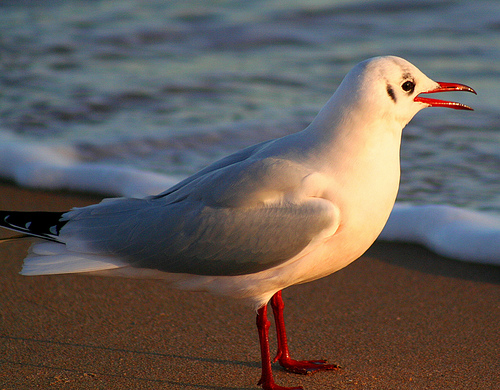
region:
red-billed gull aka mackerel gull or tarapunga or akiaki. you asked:
[4, 51, 485, 388]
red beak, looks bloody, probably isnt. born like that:
[413, 80, 480, 118]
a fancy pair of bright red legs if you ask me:
[230, 289, 360, 389]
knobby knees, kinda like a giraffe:
[253, 287, 288, 334]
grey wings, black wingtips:
[0, 140, 346, 285]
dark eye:
[398, 80, 414, 93]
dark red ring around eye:
[394, 72, 417, 100]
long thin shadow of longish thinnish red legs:
[0, 330, 337, 385]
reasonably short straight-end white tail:
[7, 236, 128, 278]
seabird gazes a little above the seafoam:
[1, 122, 498, 273]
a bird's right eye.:
[396, 71, 421, 100]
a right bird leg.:
[250, 298, 275, 388]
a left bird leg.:
[268, 270, 311, 389]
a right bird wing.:
[54, 149, 340, 318]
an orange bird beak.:
[409, 69, 489, 132]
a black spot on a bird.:
[382, 84, 399, 111]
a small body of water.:
[0, 0, 498, 285]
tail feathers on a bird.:
[7, 212, 134, 292]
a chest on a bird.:
[313, 162, 410, 276]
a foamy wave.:
[2, 128, 495, 268]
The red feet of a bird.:
[237, 294, 354, 389]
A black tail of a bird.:
[5, 194, 109, 294]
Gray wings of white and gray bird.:
[79, 171, 380, 268]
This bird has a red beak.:
[426, 72, 483, 122]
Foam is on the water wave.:
[0, 116, 173, 195]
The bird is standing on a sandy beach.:
[5, 278, 498, 388]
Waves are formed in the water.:
[24, 20, 496, 48]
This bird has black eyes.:
[397, 70, 416, 101]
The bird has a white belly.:
[337, 160, 428, 331]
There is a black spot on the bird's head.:
[385, 77, 400, 112]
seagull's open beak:
[412, 75, 479, 112]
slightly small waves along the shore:
[0, 0, 499, 265]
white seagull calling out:
[0, 55, 477, 389]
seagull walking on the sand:
[1, 54, 478, 389]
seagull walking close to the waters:
[0, 50, 499, 388]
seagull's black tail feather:
[0, 206, 73, 245]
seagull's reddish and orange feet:
[242, 278, 342, 389]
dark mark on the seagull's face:
[381, 73, 398, 105]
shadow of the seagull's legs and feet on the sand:
[0, 330, 323, 388]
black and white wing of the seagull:
[62, 155, 342, 281]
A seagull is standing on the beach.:
[0, 22, 490, 387]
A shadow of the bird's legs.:
[1, 315, 241, 385]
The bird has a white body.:
[55, 25, 411, 310]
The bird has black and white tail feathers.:
[0, 195, 70, 245]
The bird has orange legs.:
[242, 280, 295, 381]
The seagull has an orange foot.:
[268, 345, 343, 377]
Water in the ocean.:
[3, 3, 498, 243]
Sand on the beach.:
[351, 275, 492, 387]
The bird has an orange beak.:
[413, 75, 478, 115]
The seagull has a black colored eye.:
[399, 77, 416, 96]